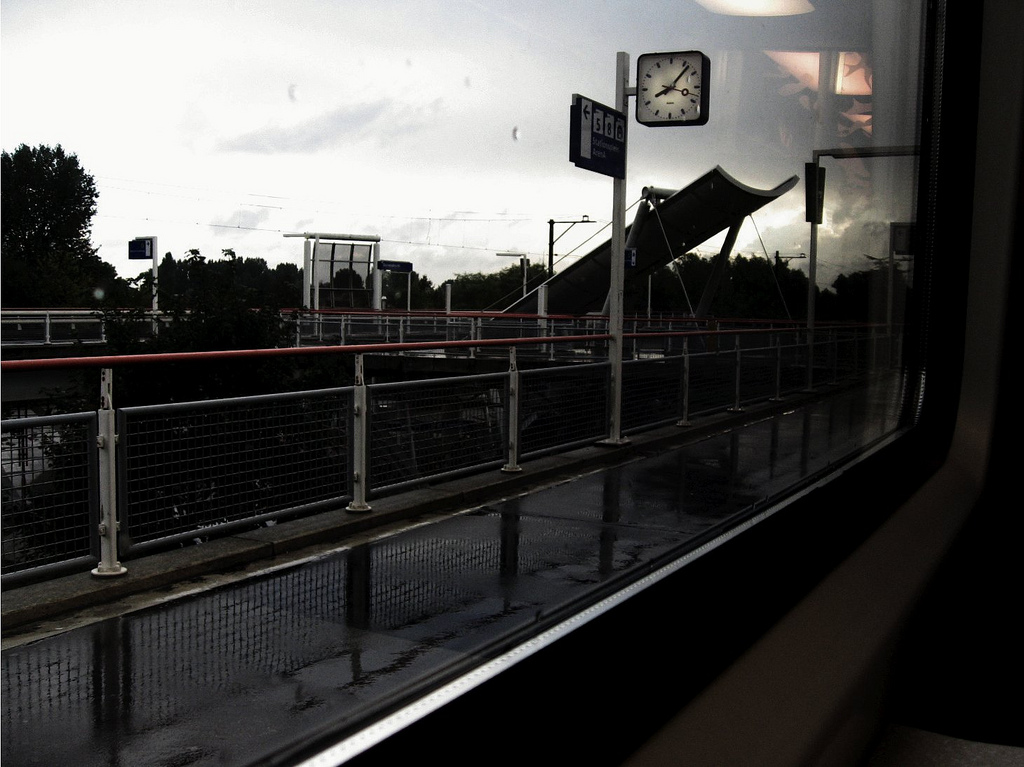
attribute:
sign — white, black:
[570, 93, 627, 179]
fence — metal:
[10, 317, 937, 758]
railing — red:
[1, 332, 827, 371]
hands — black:
[653, 68, 688, 103]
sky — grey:
[68, 50, 144, 136]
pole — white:
[80, 378, 135, 579]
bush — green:
[5, 150, 83, 246]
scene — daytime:
[87, 129, 970, 741]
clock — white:
[631, 31, 708, 143]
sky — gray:
[20, 93, 912, 231]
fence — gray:
[24, 382, 917, 695]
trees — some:
[5, 112, 1017, 398]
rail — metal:
[65, 379, 361, 414]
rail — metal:
[262, 467, 585, 558]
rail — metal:
[501, 463, 638, 513]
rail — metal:
[491, 350, 630, 387]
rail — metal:
[711, 402, 779, 441]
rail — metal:
[618, 344, 686, 373]